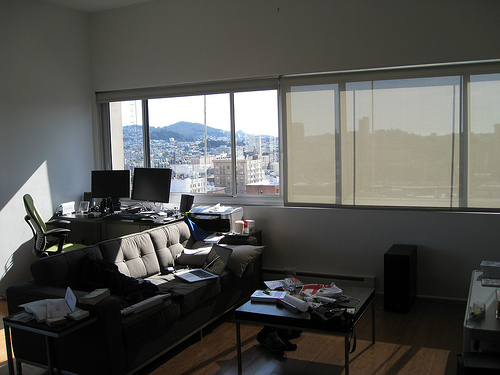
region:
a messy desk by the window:
[49, 165, 252, 234]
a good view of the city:
[116, 113, 291, 198]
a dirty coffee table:
[236, 274, 381, 364]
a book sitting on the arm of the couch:
[73, 285, 121, 322]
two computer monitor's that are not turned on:
[84, 163, 176, 210]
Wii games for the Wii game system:
[471, 252, 498, 295]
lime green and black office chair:
[11, 183, 95, 252]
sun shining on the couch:
[103, 211, 235, 288]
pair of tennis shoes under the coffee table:
[251, 312, 311, 363]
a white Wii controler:
[311, 287, 336, 309]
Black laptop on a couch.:
[10, 212, 266, 357]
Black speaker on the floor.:
[376, 235, 433, 325]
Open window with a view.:
[75, 77, 275, 207]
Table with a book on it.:
[226, 266, 381, 371]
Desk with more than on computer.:
[20, 160, 236, 256]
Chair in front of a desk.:
[15, 185, 270, 271]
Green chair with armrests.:
[15, 181, 125, 321]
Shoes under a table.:
[226, 266, 376, 371]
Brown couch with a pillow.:
[0, 215, 265, 370]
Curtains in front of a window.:
[282, 81, 499, 203]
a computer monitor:
[123, 162, 178, 218]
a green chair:
[12, 177, 105, 262]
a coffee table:
[227, 258, 386, 368]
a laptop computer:
[166, 233, 240, 290]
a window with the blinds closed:
[276, 50, 483, 233]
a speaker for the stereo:
[382, 230, 427, 327]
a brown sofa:
[8, 200, 275, 369]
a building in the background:
[173, 81, 293, 213]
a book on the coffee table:
[230, 272, 317, 325]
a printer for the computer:
[163, 191, 260, 256]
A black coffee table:
[232, 270, 386, 372]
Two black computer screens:
[85, 163, 177, 210]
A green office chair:
[17, 183, 89, 264]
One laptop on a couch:
[173, 239, 238, 294]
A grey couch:
[15, 215, 237, 369]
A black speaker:
[378, 238, 431, 319]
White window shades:
[277, 76, 497, 204]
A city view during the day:
[160, 128, 280, 189]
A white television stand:
[460, 251, 496, 369]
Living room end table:
[2, 297, 91, 370]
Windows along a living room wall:
[95, 82, 499, 204]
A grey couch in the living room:
[47, 216, 222, 351]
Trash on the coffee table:
[255, 271, 350, 320]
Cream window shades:
[292, 79, 497, 194]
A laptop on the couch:
[170, 241, 235, 293]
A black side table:
[1, 291, 97, 372]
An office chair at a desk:
[22, 190, 90, 257]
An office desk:
[64, 196, 214, 234]